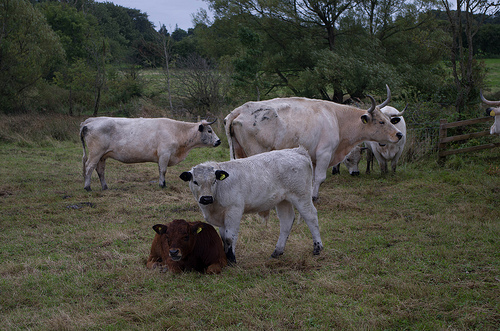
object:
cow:
[146, 219, 228, 275]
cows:
[479, 94, 500, 135]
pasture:
[3, 0, 499, 331]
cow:
[178, 143, 323, 266]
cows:
[79, 116, 221, 192]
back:
[0, 32, 499, 182]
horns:
[366, 95, 377, 113]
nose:
[199, 195, 214, 205]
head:
[179, 163, 230, 205]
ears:
[152, 224, 169, 235]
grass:
[0, 141, 500, 331]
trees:
[1, 0, 68, 114]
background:
[2, 0, 499, 198]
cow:
[223, 84, 405, 202]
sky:
[92, 0, 499, 36]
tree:
[144, 20, 182, 120]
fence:
[438, 114, 500, 168]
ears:
[215, 170, 230, 182]